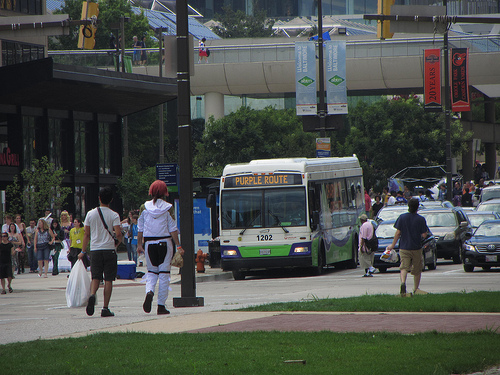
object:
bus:
[215, 153, 369, 282]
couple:
[62, 176, 188, 321]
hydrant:
[191, 246, 213, 274]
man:
[379, 195, 438, 300]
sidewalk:
[126, 305, 500, 341]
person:
[354, 212, 382, 277]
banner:
[292, 37, 320, 117]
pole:
[308, 0, 334, 139]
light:
[220, 248, 241, 259]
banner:
[418, 43, 447, 115]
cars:
[358, 214, 440, 276]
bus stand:
[172, 196, 220, 255]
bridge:
[98, 13, 500, 100]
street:
[182, 247, 398, 296]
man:
[62, 184, 131, 321]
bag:
[60, 253, 101, 310]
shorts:
[394, 246, 429, 278]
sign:
[230, 172, 298, 188]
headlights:
[291, 244, 311, 254]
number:
[255, 233, 275, 243]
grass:
[101, 338, 226, 372]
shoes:
[97, 303, 119, 318]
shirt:
[66, 225, 90, 251]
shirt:
[392, 211, 428, 252]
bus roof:
[217, 152, 366, 180]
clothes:
[131, 195, 180, 309]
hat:
[358, 212, 370, 222]